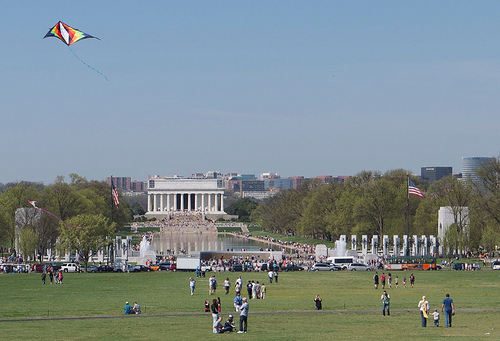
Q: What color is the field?
A: Green.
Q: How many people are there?
A: More than five.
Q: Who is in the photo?
A: People.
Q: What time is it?
A: Daytime.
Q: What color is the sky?
A: Blue.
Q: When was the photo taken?
A: Daytime.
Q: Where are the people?
A: At a park.